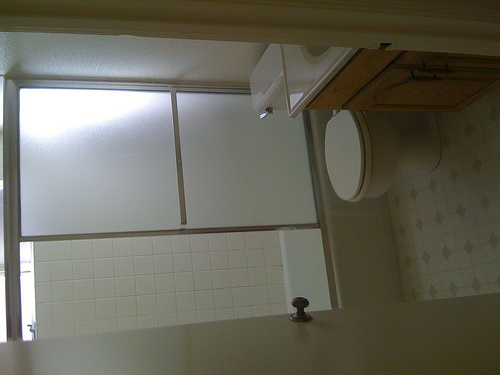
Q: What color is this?
A: White.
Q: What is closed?
A: Toilet sink.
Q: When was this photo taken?
A: In the daytime.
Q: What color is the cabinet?
A: Brown.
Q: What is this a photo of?
A: A bathroom.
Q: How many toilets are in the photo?
A: One.